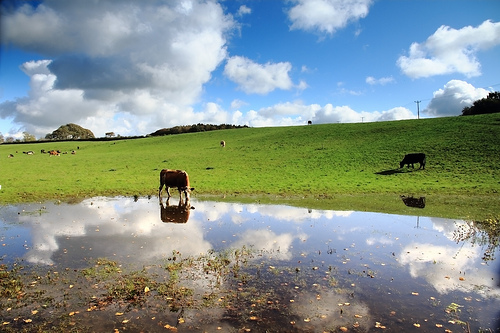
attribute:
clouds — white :
[9, 2, 230, 89]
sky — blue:
[2, 3, 497, 135]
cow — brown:
[153, 166, 198, 209]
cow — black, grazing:
[398, 141, 428, 172]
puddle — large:
[1, 190, 497, 330]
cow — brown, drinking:
[154, 167, 194, 202]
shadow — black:
[380, 162, 407, 182]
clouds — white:
[79, 23, 163, 82]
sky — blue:
[330, 46, 367, 77]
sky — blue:
[1, 2, 496, 84]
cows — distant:
[65, 147, 75, 157]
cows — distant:
[36, 146, 45, 154]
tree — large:
[48, 118, 99, 143]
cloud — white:
[393, 17, 499, 77]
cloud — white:
[284, 0, 370, 36]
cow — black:
[388, 180, 442, 210]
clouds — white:
[224, 54, 293, 96]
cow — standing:
[304, 117, 315, 124]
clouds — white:
[127, 17, 314, 104]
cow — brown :
[158, 167, 195, 202]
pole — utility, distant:
[412, 95, 423, 123]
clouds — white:
[45, 93, 87, 121]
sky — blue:
[252, 19, 286, 49]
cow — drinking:
[158, 168, 192, 197]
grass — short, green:
[0, 114, 499, 216]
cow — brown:
[156, 165, 198, 205]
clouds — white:
[12, 1, 194, 121]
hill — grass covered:
[36, 122, 479, 182]